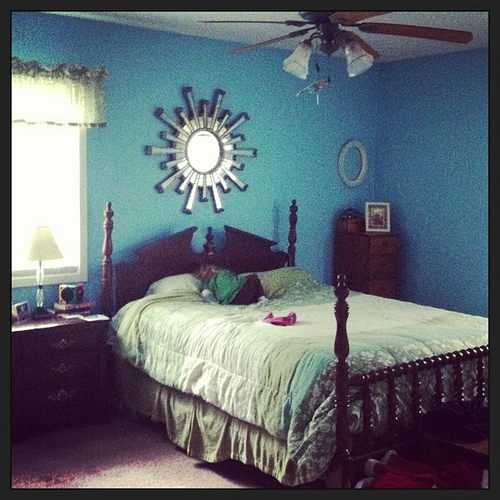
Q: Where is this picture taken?
A: Bedroom.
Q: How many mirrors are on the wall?
A: One.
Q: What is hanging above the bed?
A: Ceiling fan.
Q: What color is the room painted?
A: Blue.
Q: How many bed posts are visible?
A: Three.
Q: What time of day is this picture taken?
A: Day time.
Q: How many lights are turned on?
A: Zero.